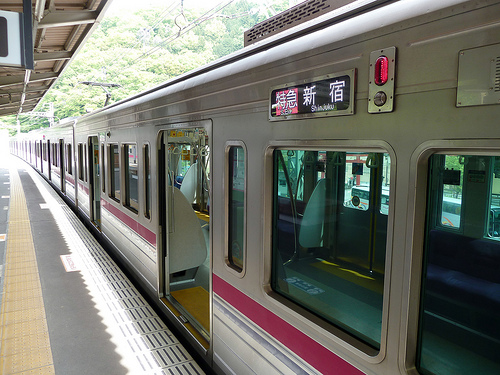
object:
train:
[6, 0, 500, 373]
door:
[155, 117, 222, 368]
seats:
[424, 231, 500, 344]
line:
[212, 271, 366, 374]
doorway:
[168, 284, 220, 349]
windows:
[257, 132, 398, 365]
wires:
[63, 1, 242, 132]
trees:
[2, 49, 210, 140]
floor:
[0, 151, 205, 374]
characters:
[272, 89, 299, 117]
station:
[0, 0, 212, 373]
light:
[372, 52, 388, 87]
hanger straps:
[170, 143, 181, 157]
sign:
[271, 73, 354, 116]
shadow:
[2, 158, 129, 374]